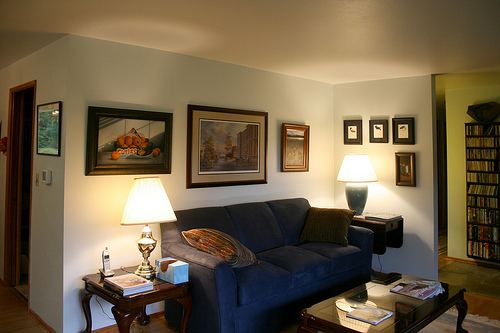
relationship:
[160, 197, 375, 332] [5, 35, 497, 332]
couch in living room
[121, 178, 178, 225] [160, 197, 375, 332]
lamp are next to couch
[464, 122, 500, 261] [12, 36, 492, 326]
bookshelf in hallway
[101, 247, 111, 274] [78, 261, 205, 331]
phone on table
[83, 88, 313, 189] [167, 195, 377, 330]
paintings are above couch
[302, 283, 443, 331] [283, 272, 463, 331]
glass on coffe table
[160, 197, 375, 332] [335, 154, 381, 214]
couch near lamp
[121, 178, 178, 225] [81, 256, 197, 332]
lamp on table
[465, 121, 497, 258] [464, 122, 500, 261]
books on bookshelf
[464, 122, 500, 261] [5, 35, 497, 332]
bookshelf near living room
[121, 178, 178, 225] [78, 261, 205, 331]
lamp on table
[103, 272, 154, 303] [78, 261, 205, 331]
book on table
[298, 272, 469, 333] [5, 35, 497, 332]
coffe table in center of living room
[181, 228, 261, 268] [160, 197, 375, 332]
pillow on couch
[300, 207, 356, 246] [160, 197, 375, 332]
pillow on couch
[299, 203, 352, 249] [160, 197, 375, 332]
pillow on couch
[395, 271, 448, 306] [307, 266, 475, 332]
magazines on table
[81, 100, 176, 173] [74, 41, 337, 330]
painting on wall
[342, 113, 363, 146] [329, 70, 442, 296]
cards on wall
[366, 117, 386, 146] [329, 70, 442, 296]
cards on wall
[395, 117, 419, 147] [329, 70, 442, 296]
cards on wall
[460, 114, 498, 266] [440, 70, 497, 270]
bookshelf on wall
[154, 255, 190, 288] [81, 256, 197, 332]
box on table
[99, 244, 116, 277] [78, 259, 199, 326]
phone on table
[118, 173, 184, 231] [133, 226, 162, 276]
lampshade on base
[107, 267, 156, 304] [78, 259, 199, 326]
book on table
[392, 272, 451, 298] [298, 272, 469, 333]
newspaper on coffe table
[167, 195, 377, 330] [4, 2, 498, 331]
couch in room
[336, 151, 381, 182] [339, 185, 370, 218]
lampshade over base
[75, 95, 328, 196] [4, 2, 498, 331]
pictures in room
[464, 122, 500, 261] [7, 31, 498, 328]
bookshelf in room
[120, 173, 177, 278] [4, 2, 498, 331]
lamp in room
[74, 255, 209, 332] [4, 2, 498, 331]
table in room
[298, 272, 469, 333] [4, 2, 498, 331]
coffe table in room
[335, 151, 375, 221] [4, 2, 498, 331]
lamp in room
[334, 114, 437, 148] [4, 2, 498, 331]
pictures in room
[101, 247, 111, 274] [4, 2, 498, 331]
phone in room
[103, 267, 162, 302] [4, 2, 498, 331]
book in room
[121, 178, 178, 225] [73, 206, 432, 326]
lamp on tables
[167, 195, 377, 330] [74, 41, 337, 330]
couch against wall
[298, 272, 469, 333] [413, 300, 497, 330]
coffe table on rug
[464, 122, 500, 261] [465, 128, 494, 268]
bookshelf of books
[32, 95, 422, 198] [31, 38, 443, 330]
pictures on wall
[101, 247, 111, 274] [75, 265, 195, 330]
phone on table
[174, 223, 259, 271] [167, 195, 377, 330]
pillow on couch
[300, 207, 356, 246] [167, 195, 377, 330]
pillow on couch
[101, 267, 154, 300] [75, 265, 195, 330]
book on table